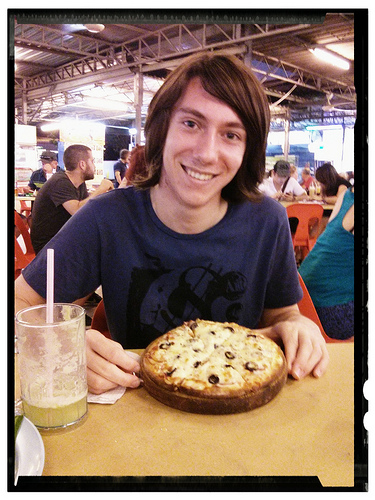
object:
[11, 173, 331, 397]
body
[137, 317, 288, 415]
pizza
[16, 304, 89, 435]
glass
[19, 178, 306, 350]
shirt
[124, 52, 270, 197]
long hair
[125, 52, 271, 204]
head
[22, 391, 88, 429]
liquid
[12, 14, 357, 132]
roof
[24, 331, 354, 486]
table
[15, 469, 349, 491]
laptop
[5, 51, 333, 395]
man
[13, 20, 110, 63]
railings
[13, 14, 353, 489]
photo